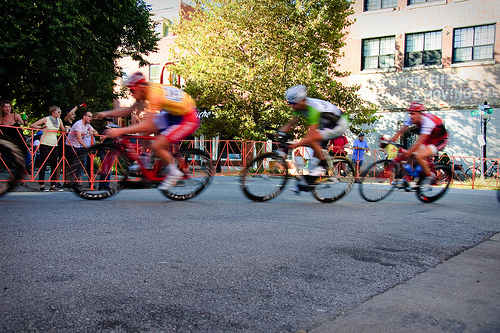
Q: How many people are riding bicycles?
A: 3.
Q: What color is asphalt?
A: Black.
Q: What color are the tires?
A: Black.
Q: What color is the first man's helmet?
A: Red.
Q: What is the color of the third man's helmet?
A: Red.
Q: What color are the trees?
A: Green.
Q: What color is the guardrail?
A: Orange.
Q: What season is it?
A: Summer.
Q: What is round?
A: Wheels.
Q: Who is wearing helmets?
A: Bicycle riders.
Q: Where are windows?
A: On a building.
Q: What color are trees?
A: Green.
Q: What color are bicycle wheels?
A: Black.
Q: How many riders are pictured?
A: Three.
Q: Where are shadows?
A: On the building.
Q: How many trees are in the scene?
A: Two.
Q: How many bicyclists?
A: 3.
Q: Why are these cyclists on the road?
A: Racing.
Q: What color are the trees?
A: Green.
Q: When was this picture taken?
A: During a race.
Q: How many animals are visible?
A: 0.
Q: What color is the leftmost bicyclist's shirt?
A: Orange.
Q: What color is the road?
A: Grey.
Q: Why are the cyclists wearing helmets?
A: Protection.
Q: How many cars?
A: 0.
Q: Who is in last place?
A: Man in red.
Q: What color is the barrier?
A: Orange.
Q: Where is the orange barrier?
A: In front of the crowd.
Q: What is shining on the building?
A: Sunlight.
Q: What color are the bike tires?
A: Black.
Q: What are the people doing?
A: Racing.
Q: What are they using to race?
A: Bikes.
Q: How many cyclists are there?
A: Three.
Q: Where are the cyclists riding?
A: On the road.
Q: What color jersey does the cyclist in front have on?
A: Orange.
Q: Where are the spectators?
A: Behind the fence.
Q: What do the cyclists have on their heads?
A: Helmets.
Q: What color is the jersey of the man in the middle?
A: Green.